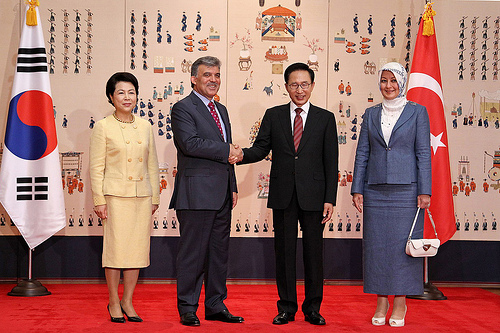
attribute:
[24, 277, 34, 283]
holder — flag pole holder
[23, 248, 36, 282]
pole — flag pole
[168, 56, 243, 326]
man — standing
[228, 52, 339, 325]
man — standing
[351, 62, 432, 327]
woman — standing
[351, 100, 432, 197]
jacket — blue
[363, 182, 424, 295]
skirt — blue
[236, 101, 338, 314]
suit — black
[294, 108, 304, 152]
tie — red, grey, brown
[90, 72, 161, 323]
woman — standing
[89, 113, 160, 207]
jacket — yellow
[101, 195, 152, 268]
skirt — yellow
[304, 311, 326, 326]
shoe — black, shiny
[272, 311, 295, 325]
shoe — black, shiny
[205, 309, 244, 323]
shoe — black, shiny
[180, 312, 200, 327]
shoe — black, shiny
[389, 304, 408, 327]
shoe — white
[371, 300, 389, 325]
shoe — white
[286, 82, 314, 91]
glasses — clear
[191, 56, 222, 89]
hair — brown, grey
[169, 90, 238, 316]
suit — blue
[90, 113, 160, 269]
outfit — yellow, beige, light yellow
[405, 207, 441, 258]
purse — white, small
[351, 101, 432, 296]
outfit — grey, denim blue, denim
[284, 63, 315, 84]
hair — thick, black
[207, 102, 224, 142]
tie — red, white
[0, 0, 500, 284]
wall — painted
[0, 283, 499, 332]
carpet — bright red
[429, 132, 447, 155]
star — white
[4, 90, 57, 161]
circle — blue, red